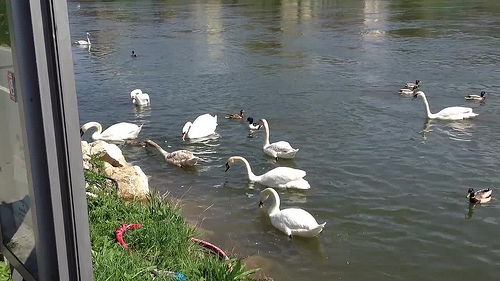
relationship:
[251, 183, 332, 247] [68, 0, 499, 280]
swan in water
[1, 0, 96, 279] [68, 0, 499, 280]
building by water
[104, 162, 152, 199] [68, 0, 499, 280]
rock near water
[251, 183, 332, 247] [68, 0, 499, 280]
swan swimming in water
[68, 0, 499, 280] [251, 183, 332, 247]
water with a swan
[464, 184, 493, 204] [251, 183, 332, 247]
duck and swan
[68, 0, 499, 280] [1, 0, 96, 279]
water by building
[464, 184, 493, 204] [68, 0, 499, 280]
duck in water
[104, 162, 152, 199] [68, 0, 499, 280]
rock by water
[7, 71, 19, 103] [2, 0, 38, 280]
sticker on glass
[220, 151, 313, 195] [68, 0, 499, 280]
bird in water